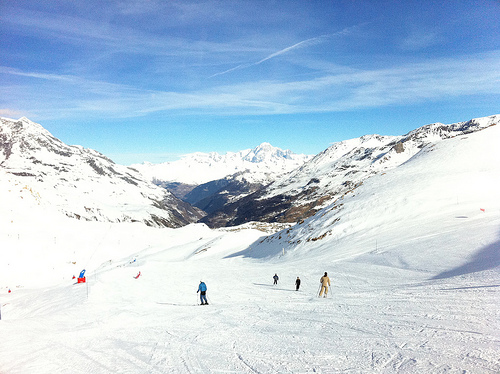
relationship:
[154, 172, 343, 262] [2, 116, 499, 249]
shade from mountain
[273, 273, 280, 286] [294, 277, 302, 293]
person next to person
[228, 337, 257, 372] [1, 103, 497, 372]
track in snow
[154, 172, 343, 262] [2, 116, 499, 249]
shade on mountain